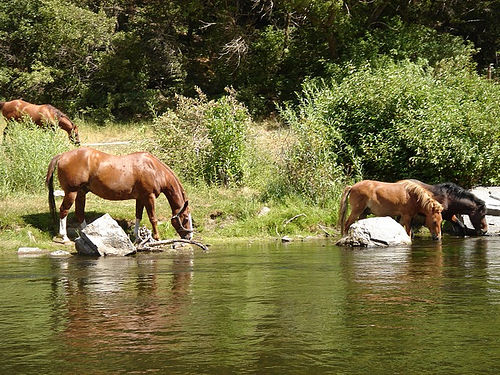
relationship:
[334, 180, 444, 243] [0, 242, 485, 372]
horse on water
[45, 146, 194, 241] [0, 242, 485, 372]
horse drinking water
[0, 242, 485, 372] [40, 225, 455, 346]
water from pond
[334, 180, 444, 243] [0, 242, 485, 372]
horse drinking water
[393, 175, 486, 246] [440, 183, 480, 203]
horse has mane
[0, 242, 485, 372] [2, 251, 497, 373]
water in lake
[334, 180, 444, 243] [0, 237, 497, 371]
horse drinks from pond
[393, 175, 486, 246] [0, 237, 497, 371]
horse drinks from pond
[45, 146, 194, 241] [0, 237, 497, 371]
horse drinks from pond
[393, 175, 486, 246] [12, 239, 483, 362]
horse drinking water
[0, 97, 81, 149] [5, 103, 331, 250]
horse on grass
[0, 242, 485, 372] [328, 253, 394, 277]
water in lake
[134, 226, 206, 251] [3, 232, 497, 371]
branch near lake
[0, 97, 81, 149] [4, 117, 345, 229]
horse grazing in grass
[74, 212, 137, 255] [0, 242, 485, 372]
rock next to water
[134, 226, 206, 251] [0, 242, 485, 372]
branch next to water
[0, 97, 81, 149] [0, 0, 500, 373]
horse in wilderness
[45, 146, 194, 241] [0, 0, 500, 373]
horse in wilderness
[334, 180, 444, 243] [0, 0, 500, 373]
horse in wilderness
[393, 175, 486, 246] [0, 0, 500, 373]
horse in wilderness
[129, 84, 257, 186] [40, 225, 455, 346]
bush by pond